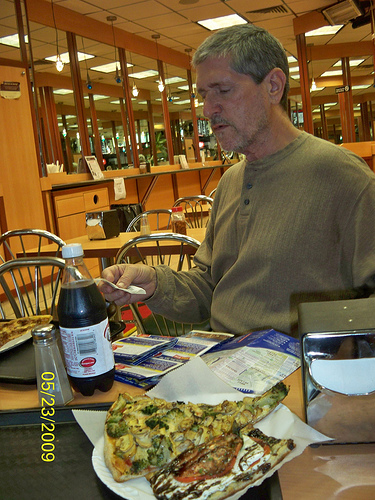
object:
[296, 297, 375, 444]
napkin dispenser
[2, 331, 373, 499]
table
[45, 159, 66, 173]
straws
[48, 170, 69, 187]
box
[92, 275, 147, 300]
napkin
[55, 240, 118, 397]
bottle of soda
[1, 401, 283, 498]
food tray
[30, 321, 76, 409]
pepper shaker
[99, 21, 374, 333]
man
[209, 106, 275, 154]
beard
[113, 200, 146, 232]
trash can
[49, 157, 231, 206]
counter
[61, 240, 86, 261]
bottle cap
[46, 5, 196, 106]
lights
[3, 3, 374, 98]
ceiling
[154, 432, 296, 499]
pizza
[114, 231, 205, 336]
chair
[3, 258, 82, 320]
chair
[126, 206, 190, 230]
chair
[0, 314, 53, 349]
pizza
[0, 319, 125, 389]
food tray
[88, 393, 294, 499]
paper plate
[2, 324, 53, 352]
paper plate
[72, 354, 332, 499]
paper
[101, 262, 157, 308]
hand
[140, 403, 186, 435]
vegetables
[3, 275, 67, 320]
floor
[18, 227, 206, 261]
table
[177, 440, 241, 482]
tomato